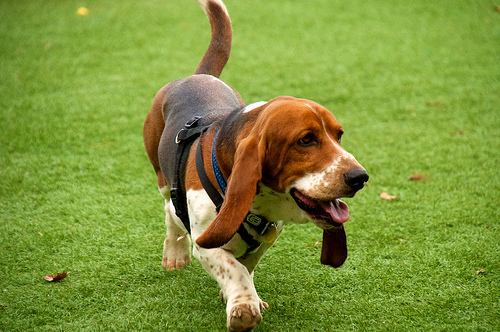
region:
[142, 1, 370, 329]
a brown beagle dog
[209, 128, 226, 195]
blue collar around dog's neck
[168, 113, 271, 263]
black harness on dog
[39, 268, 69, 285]
brown leaf on grass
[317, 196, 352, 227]
dog's tongue sticking out of mouth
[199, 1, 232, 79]
brown tail sticking up in air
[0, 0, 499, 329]
dog running in green grass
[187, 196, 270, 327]
white front leg with brown speckles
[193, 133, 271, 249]
long brown ear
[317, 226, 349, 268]
bottom back of ear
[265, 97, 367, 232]
the face of a dog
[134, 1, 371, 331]
a small brown and white dog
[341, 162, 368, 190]
a dog's nose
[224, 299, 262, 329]
a dog's front paw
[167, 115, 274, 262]
a harness on a dog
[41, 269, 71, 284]
a leaf on grass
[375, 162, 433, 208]
leaves in grass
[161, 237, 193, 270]
the back paw of a dog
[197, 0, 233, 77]
the tail of a dog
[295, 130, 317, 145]
a dog's right eye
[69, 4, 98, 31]
yellow ball in green grass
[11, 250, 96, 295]
brown leaf laying in grass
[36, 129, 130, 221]
field covered in thick green grass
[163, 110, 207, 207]
black harness on dog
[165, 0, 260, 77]
brown and white dog tail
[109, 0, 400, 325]
brown and white dog walking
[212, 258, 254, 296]
brown spots on leg of dog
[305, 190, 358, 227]
pink dog tongue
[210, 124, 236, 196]
blue collar on dog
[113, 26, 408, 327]
dog with brown floppy ears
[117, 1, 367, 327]
a dog walking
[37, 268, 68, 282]
a brown leaf on the grass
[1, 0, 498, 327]
short cut green grass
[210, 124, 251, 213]
a blue collar on a dog's neck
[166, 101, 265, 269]
a black harness on a dog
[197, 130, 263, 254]
a long brown dog ear hanging down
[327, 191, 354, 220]
a pink dog tongue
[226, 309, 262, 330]
the pads on the bottom of a dog's foot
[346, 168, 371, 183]
a black nose on a dog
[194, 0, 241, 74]
a brown tail on a dog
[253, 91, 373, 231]
the head of a dog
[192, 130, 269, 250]
the ear of a dog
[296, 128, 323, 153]
the eye of a dog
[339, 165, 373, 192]
the nose of a dog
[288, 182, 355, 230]
the mouth of a dog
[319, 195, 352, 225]
the tongue of a dog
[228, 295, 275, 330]
the paw of a dog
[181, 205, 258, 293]
the leg of a dog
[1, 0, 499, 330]
a grassy green field